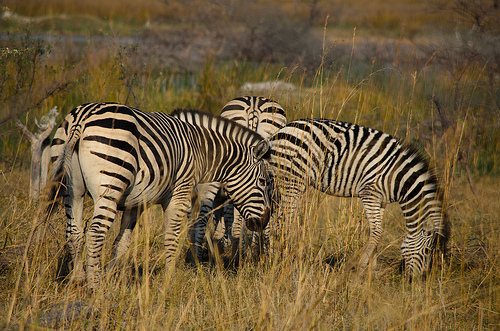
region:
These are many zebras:
[81, 68, 459, 294]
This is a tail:
[30, 122, 85, 194]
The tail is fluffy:
[17, 170, 89, 246]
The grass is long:
[0, 213, 327, 315]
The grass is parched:
[263, 251, 309, 277]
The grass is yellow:
[205, 236, 355, 294]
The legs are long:
[156, 203, 266, 318]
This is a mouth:
[230, 210, 303, 225]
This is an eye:
[247, 171, 269, 192]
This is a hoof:
[330, 261, 362, 278]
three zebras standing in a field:
[35, 77, 432, 286]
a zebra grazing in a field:
[263, 110, 462, 287]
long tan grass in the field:
[266, 280, 449, 327]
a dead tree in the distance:
[126, 5, 378, 68]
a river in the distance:
[44, 33, 118, 55]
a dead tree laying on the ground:
[0, 3, 114, 28]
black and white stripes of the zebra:
[124, 121, 202, 183]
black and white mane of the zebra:
[401, 148, 444, 225]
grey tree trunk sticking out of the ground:
[14, 99, 57, 213]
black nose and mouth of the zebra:
[240, 208, 278, 238]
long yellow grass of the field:
[235, 271, 405, 321]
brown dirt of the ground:
[7, 234, 42, 275]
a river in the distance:
[36, 32, 140, 46]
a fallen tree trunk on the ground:
[1, 7, 113, 32]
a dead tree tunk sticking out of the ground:
[16, 112, 58, 208]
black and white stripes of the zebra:
[315, 139, 377, 183]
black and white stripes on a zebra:
[145, 126, 175, 174]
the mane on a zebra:
[406, 137, 456, 229]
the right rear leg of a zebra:
[82, 177, 115, 292]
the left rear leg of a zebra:
[50, 165, 77, 275]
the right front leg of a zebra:
[165, 186, 190, 267]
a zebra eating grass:
[266, 115, 441, 275]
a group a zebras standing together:
[30, 82, 451, 282]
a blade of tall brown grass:
[311, 15, 341, 105]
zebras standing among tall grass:
[36, 82, 451, 303]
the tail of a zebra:
[42, 120, 86, 217]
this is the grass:
[254, 263, 346, 323]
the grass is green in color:
[281, 251, 344, 314]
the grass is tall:
[218, 265, 319, 318]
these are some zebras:
[47, 82, 475, 292]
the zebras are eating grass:
[42, 85, 452, 284]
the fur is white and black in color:
[172, 128, 216, 166]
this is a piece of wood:
[23, 117, 51, 184]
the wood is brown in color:
[25, 127, 49, 197]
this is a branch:
[0, 35, 62, 114]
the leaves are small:
[14, 30, 59, 70]